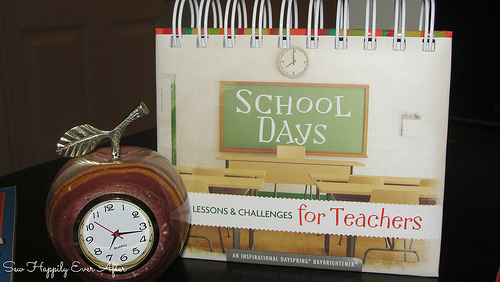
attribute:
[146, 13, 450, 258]
book — small, spiral bound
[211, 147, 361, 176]
desk — wooden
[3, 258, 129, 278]
lettering — cursive, white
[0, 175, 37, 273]
book — blue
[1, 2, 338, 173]
door — wooden, light colored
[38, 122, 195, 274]
clock — fancy, decorative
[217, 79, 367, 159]
chalkboard — green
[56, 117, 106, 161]
leaf — gold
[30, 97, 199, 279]
clock — apple shaped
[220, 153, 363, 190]
desk — tan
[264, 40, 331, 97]
clock — white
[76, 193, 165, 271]
clock — apple shaped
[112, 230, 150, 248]
hand — black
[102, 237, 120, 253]
hand — black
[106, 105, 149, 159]
stem — gold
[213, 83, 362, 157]
chalk board — green